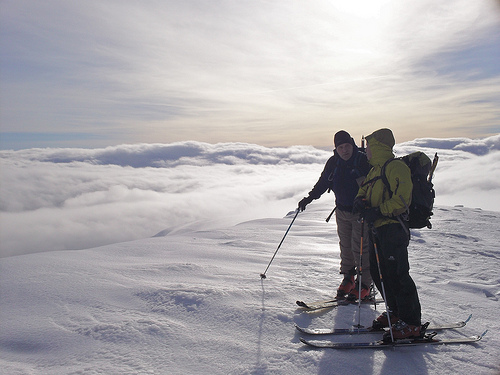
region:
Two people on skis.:
[253, 122, 497, 352]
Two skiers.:
[247, 129, 493, 351]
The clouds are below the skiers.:
[1, 134, 495, 249]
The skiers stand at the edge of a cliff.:
[1, 193, 498, 374]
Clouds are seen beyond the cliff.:
[8, 124, 499, 256]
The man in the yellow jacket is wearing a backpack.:
[298, 125, 483, 354]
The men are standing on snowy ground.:
[240, 117, 495, 353]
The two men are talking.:
[243, 118, 498, 351]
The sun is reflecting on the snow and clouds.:
[11, 125, 494, 372]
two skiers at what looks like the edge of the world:
[1, 121, 492, 348]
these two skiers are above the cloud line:
[1, 122, 497, 260]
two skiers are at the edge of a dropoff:
[2, 195, 498, 373]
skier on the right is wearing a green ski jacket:
[352, 124, 422, 236]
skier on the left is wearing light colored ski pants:
[328, 204, 385, 291]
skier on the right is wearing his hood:
[359, 125, 401, 174]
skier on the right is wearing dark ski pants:
[364, 217, 429, 330]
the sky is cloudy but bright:
[7, 3, 496, 128]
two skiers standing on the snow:
[260, 120, 492, 360]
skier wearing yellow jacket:
[360, 128, 449, 343]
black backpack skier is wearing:
[367, 151, 438, 226]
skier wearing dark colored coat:
[301, 133, 371, 295]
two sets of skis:
[283, 293, 488, 353]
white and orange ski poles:
[333, 220, 405, 345]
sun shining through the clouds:
[265, 3, 399, 80]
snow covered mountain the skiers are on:
[9, 148, 499, 373]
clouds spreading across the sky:
[11, 1, 498, 141]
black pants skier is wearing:
[369, 227, 429, 322]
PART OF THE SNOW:
[57, 268, 265, 370]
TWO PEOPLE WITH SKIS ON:
[267, 113, 484, 372]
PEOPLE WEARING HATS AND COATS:
[308, 123, 415, 229]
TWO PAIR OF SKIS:
[275, 278, 485, 369]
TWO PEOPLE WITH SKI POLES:
[235, 108, 487, 360]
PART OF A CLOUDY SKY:
[142, 135, 243, 204]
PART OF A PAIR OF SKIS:
[292, 304, 379, 354]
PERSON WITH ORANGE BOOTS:
[331, 257, 375, 306]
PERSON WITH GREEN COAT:
[330, 119, 421, 240]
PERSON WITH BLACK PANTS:
[369, 193, 466, 352]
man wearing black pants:
[394, 275, 404, 291]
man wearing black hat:
[336, 132, 346, 142]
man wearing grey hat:
[381, 130, 389, 140]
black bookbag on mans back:
[411, 153, 437, 230]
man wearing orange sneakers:
[338, 282, 367, 301]